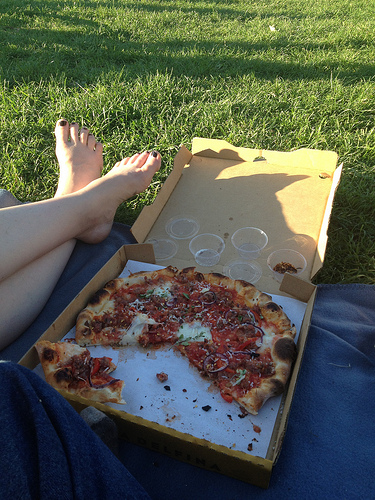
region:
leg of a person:
[65, 140, 183, 253]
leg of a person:
[21, 120, 130, 210]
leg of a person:
[4, 181, 79, 264]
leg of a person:
[1, 226, 76, 319]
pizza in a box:
[37, 345, 144, 397]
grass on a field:
[85, 45, 123, 83]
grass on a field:
[223, 64, 260, 96]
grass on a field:
[315, 109, 349, 141]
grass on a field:
[312, 18, 340, 54]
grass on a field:
[22, 15, 61, 45]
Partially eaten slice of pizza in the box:
[33, 335, 131, 401]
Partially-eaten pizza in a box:
[18, 255, 299, 477]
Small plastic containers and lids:
[144, 214, 309, 285]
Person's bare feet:
[49, 116, 163, 240]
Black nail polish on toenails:
[134, 149, 162, 156]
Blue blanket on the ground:
[0, 191, 373, 497]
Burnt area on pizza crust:
[275, 333, 299, 362]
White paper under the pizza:
[34, 254, 309, 456]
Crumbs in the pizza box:
[154, 373, 264, 452]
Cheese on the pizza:
[118, 309, 154, 347]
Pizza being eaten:
[65, 265, 300, 413]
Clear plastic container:
[227, 225, 268, 259]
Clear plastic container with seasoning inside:
[266, 247, 306, 285]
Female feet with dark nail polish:
[46, 114, 164, 250]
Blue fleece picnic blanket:
[2, 187, 374, 493]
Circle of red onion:
[201, 348, 231, 377]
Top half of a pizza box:
[120, 131, 346, 274]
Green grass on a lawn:
[3, 4, 370, 133]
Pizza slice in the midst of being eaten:
[32, 337, 123, 402]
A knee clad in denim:
[1, 352, 153, 496]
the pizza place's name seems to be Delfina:
[114, 421, 238, 477]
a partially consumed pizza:
[17, 237, 318, 492]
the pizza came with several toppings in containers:
[136, 209, 314, 298]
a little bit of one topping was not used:
[263, 242, 310, 284]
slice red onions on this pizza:
[199, 350, 231, 376]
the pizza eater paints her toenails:
[48, 111, 164, 180]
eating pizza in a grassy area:
[13, 12, 360, 190]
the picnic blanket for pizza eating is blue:
[2, 199, 373, 496]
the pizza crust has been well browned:
[255, 293, 298, 399]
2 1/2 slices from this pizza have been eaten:
[28, 322, 267, 432]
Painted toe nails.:
[50, 116, 104, 155]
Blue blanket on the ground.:
[1, 219, 371, 497]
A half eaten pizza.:
[36, 262, 297, 416]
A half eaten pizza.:
[18, 134, 343, 490]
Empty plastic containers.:
[188, 225, 267, 267]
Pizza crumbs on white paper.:
[133, 369, 199, 412]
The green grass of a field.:
[0, 1, 372, 284]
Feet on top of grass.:
[50, 114, 162, 244]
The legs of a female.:
[2, 114, 164, 353]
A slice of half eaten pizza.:
[32, 338, 129, 408]